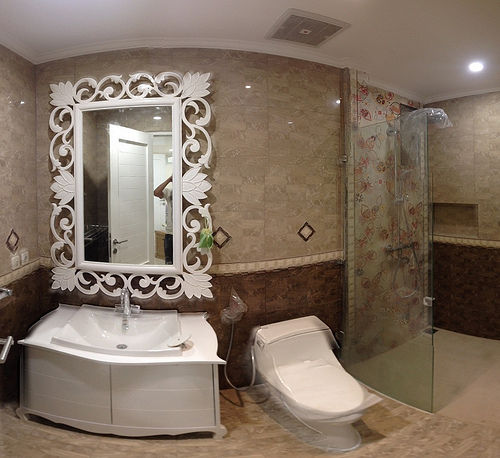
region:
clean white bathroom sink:
[34, 300, 222, 437]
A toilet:
[248, 305, 373, 445]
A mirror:
[80, 107, 175, 259]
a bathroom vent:
[270, 2, 330, 59]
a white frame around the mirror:
[47, 82, 207, 297]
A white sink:
[70, 296, 185, 351]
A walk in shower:
[376, 136, 498, 416]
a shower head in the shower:
[404, 98, 456, 145]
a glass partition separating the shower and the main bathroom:
[349, 117, 444, 419]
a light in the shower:
[460, 43, 499, 82]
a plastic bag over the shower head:
[388, 101, 452, 168]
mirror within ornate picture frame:
[39, 73, 239, 303]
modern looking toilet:
[242, 309, 404, 451]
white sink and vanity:
[10, 281, 255, 445]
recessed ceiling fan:
[257, 5, 380, 74]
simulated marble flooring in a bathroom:
[408, 420, 473, 450]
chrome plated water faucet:
[103, 273, 153, 319]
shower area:
[346, 103, 496, 428]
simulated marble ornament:
[289, 213, 320, 248]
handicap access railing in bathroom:
[0, 324, 24, 391]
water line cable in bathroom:
[195, 284, 291, 405]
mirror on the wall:
[1, 81, 250, 283]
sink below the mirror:
[88, 282, 169, 355]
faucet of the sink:
[94, 285, 151, 336]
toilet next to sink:
[231, 281, 373, 443]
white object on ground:
[235, 303, 389, 456]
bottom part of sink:
[68, 369, 181, 441]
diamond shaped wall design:
[273, 218, 326, 263]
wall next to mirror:
[241, 202, 273, 237]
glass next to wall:
[363, 228, 450, 284]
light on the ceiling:
[448, 36, 487, 101]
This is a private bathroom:
[12, 27, 489, 440]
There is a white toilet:
[238, 296, 384, 456]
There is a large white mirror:
[25, 57, 230, 319]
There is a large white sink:
[12, 270, 232, 442]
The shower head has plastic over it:
[405, 82, 455, 194]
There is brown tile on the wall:
[10, 35, 397, 398]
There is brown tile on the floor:
[12, 349, 499, 451]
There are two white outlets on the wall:
[1, 230, 49, 295]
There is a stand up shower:
[340, 70, 498, 414]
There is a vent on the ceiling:
[250, 0, 373, 69]